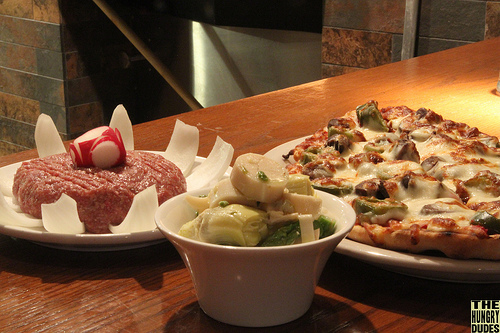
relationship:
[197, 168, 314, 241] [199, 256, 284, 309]
salad in bowl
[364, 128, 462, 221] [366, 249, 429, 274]
pizza on plate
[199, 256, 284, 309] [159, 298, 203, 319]
bowl casts shadow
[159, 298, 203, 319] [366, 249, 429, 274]
shadow on plate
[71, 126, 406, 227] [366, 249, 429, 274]
food on plate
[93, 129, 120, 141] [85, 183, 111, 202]
radish on beef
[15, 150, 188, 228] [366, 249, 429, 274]
beef on plate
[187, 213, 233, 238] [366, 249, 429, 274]
dumplings in plate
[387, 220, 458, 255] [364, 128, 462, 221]
crust of pizza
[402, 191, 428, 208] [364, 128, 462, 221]
cheese on pizza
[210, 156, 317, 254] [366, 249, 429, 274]
vegetables on plate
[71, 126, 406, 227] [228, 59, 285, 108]
food on table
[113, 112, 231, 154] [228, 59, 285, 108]
dessert on table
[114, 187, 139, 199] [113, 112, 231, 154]
peppermint on dessert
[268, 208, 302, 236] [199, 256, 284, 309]
artichoke in bowl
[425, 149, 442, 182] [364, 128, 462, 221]
mushroom on pizza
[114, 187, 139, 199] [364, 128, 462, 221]
peppermint on pizza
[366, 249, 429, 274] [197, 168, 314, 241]
plate of salad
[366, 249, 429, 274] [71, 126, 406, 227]
plate of food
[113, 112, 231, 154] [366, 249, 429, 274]
dessert on plate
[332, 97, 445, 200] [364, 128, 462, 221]
topping on pizza